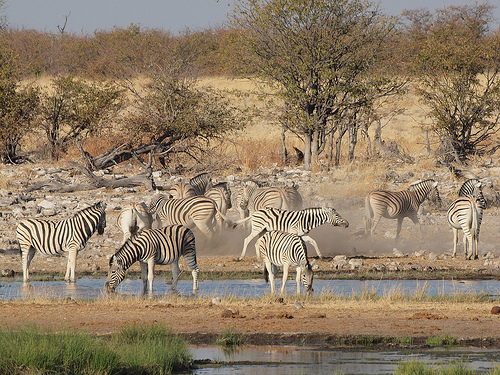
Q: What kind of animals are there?
A: Zebras.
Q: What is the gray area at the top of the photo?
A: The sky.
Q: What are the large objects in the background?
A: Trees.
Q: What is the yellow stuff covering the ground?
A: Grass.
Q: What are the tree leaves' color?
A: Green.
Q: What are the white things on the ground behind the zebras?
A: Rocks.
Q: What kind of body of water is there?
A: A stream.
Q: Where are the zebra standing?
A: In stream.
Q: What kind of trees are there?
A: Brown and green leaves.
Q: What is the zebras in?
A: Groups.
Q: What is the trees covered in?
A: Green leaves.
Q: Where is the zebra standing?
A: In water.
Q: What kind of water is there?
A: Muddy.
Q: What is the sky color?
A: Blue.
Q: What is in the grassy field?
A: Dry.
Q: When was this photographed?
A: Daytime.